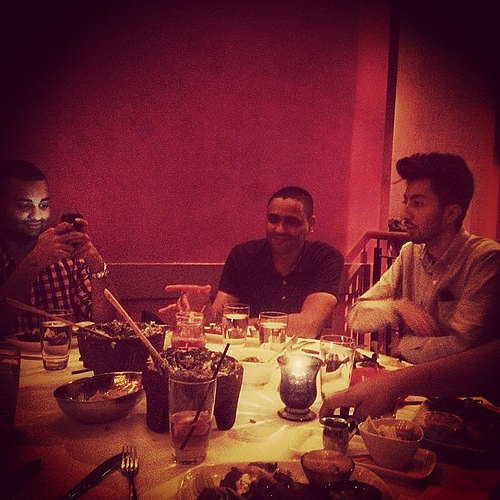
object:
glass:
[258, 310, 290, 349]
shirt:
[0, 234, 102, 337]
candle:
[277, 352, 323, 421]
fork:
[117, 440, 144, 500]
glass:
[166, 372, 218, 466]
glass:
[38, 318, 74, 371]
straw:
[178, 340, 232, 451]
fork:
[62, 448, 132, 500]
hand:
[316, 373, 399, 432]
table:
[0, 314, 500, 500]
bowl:
[51, 371, 148, 424]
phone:
[59, 210, 85, 249]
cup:
[316, 333, 358, 410]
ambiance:
[0, 315, 500, 500]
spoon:
[102, 285, 185, 384]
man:
[345, 147, 500, 374]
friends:
[0, 155, 124, 339]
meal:
[0, 320, 500, 500]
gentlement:
[152, 185, 347, 341]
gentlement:
[338, 147, 499, 378]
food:
[140, 346, 245, 433]